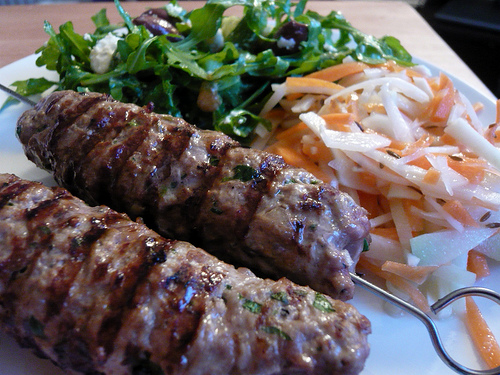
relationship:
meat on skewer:
[16, 89, 371, 299] [0, 82, 499, 373]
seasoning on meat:
[242, 291, 333, 340] [0, 172, 372, 373]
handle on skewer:
[429, 285, 499, 374] [350, 273, 499, 373]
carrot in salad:
[284, 74, 342, 95] [248, 56, 498, 373]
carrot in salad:
[308, 60, 368, 81] [248, 56, 498, 373]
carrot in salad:
[274, 111, 353, 141] [248, 56, 498, 373]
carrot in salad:
[421, 70, 456, 126] [248, 56, 498, 373]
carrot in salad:
[441, 196, 474, 225] [248, 56, 498, 373]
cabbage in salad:
[322, 76, 428, 103] [248, 56, 498, 373]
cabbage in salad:
[378, 82, 412, 146] [248, 56, 498, 373]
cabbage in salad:
[444, 116, 499, 171] [248, 56, 498, 373]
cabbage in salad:
[329, 155, 377, 193] [248, 56, 498, 373]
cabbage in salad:
[410, 227, 499, 268] [248, 56, 498, 373]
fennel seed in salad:
[423, 122, 439, 132] [248, 56, 498, 373]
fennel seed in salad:
[446, 154, 467, 164] [248, 56, 498, 373]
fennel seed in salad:
[383, 149, 403, 159] [248, 56, 498, 373]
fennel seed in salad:
[436, 198, 449, 208] [248, 56, 498, 373]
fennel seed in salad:
[476, 209, 494, 223] [248, 56, 498, 373]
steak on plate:
[0, 173, 371, 373] [0, 26, 499, 373]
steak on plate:
[14, 88, 371, 300] [0, 26, 499, 373]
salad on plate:
[1, 0, 411, 138] [0, 26, 499, 373]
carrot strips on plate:
[269, 58, 499, 373] [0, 26, 499, 373]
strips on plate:
[312, 93, 458, 219] [22, 12, 484, 359]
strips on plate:
[124, 13, 251, 76] [29, 15, 482, 290]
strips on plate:
[150, 25, 310, 78] [22, 12, 484, 359]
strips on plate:
[131, 32, 254, 82] [29, 15, 482, 290]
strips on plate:
[119, 15, 308, 107] [4, 9, 446, 372]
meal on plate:
[23, 3, 484, 370] [22, 12, 484, 359]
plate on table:
[22, 12, 484, 359] [11, 2, 86, 52]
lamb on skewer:
[43, 96, 337, 293] [10, 81, 461, 371]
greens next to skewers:
[94, 19, 303, 101] [5, 69, 484, 361]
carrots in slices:
[303, 77, 476, 223] [340, 104, 465, 228]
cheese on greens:
[78, 22, 162, 88] [80, 17, 296, 84]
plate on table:
[22, 12, 484, 359] [14, 5, 52, 51]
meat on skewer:
[64, 122, 372, 372] [369, 245, 481, 363]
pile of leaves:
[113, 17, 297, 80] [119, 6, 290, 97]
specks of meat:
[226, 257, 359, 349] [31, 175, 336, 366]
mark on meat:
[73, 190, 273, 327] [120, 132, 315, 260]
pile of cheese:
[344, 75, 458, 188] [302, 85, 480, 240]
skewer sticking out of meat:
[0, 77, 35, 110] [7, 87, 386, 277]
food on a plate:
[28, 10, 480, 305] [1, 31, 467, 364]